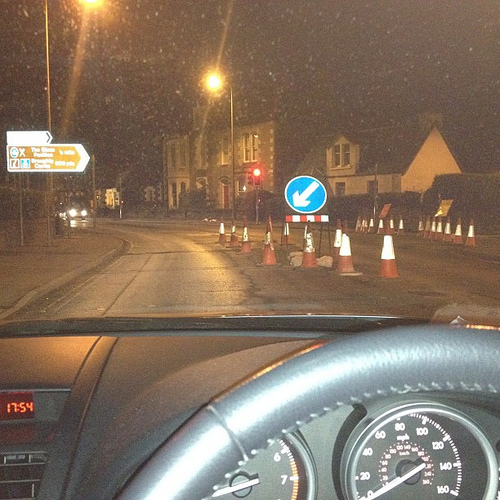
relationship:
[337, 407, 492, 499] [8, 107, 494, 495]
speedometer on car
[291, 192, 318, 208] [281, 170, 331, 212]
arrow on sign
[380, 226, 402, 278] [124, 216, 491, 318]
cone on street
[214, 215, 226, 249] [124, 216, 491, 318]
cone on street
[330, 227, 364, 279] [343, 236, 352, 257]
cone with reflector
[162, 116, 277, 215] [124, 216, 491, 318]
building next to street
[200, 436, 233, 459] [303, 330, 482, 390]
light refleciting on steering  wheel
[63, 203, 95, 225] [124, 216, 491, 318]
car on street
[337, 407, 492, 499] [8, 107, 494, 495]
speedometer in car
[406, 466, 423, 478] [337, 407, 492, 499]
needle on speedometer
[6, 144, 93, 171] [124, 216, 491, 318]
sign on street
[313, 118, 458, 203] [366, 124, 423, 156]
building has roof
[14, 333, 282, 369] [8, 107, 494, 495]
dash inside car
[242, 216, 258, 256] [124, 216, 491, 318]
cone sitting on street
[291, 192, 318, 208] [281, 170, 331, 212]
arrow painted on sign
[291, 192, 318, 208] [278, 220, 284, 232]
arrow pointing down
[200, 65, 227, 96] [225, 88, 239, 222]
streetlight on pole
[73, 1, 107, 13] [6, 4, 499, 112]
streetlight against sky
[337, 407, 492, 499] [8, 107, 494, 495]
speedometer inside of car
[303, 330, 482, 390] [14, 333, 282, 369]
steering  wheel connected to dash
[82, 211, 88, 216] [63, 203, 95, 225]
headlight on car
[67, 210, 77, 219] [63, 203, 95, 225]
headlight on car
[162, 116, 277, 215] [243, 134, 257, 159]
building has window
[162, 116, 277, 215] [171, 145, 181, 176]
building has window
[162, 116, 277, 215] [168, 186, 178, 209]
building has window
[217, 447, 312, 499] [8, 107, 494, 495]
tachometer inside of car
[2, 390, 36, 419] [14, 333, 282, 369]
clock under dash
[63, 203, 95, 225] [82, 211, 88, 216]
car with headlight